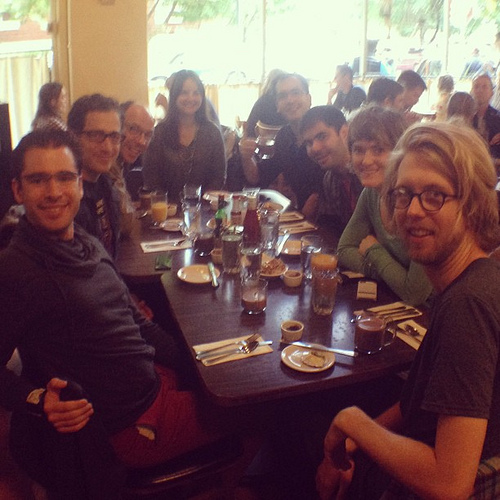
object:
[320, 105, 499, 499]
man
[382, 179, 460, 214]
glasses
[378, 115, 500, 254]
hair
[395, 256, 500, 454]
shirt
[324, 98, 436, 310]
woman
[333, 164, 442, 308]
shirt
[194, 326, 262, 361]
fork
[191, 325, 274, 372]
napkin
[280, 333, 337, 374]
plate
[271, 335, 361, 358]
knife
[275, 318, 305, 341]
cup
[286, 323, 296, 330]
coffee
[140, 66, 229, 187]
woman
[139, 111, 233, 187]
shirt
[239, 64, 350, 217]
man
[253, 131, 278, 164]
drink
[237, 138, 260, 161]
hand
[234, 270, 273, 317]
mug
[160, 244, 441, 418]
table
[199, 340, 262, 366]
silverware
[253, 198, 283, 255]
glass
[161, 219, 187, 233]
bowl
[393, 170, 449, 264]
face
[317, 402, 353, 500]
hand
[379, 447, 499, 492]
chair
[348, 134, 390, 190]
face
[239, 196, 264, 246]
bottle